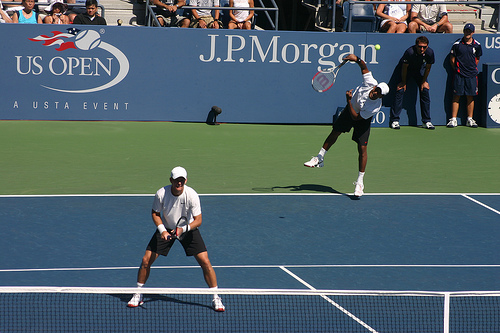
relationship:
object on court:
[204, 106, 223, 126] [2, 119, 499, 332]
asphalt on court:
[1, 121, 499, 194] [2, 119, 499, 332]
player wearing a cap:
[126, 165, 225, 312] [169, 166, 188, 180]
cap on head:
[169, 166, 188, 180] [170, 168, 188, 193]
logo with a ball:
[16, 28, 131, 97] [74, 29, 100, 54]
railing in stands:
[142, 1, 280, 28] [1, 1, 497, 34]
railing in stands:
[292, 1, 496, 32] [1, 1, 497, 34]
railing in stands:
[0, 3, 105, 26] [1, 1, 497, 34]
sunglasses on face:
[417, 45, 428, 51] [416, 41, 428, 56]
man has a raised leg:
[304, 54, 390, 199] [302, 106, 353, 170]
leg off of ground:
[302, 106, 353, 170] [2, 121, 499, 333]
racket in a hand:
[310, 59, 348, 94] [343, 53, 358, 65]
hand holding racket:
[343, 53, 358, 65] [310, 59, 348, 94]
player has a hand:
[304, 54, 390, 199] [343, 53, 358, 65]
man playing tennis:
[304, 54, 390, 199] [1, 25, 500, 332]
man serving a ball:
[304, 54, 390, 199] [374, 43, 380, 52]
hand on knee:
[396, 82, 408, 93] [394, 78, 408, 94]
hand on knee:
[420, 79, 431, 93] [419, 79, 429, 96]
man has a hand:
[390, 36, 436, 130] [396, 82, 408, 93]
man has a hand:
[390, 36, 436, 130] [420, 79, 431, 93]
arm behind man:
[449, 40, 459, 69] [446, 25, 486, 129]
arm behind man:
[476, 43, 483, 67] [446, 25, 486, 129]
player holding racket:
[126, 165, 225, 312] [169, 217, 190, 244]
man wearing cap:
[304, 54, 390, 199] [372, 82, 389, 97]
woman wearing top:
[11, 1, 43, 24] [18, 10, 38, 24]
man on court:
[390, 36, 436, 130] [2, 119, 499, 332]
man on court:
[446, 25, 486, 129] [2, 119, 499, 332]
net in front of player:
[1, 286, 499, 332] [126, 165, 225, 312]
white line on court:
[277, 263, 376, 332] [0, 194, 499, 333]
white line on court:
[2, 263, 500, 275] [0, 194, 499, 333]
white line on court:
[463, 194, 500, 215] [0, 194, 499, 333]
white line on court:
[1, 194, 500, 199] [0, 194, 499, 333]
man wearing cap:
[446, 25, 486, 129] [463, 23, 474, 35]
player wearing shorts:
[126, 165, 225, 312] [147, 226, 207, 257]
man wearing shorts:
[304, 54, 390, 199] [332, 106, 371, 146]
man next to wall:
[390, 36, 436, 130] [0, 25, 499, 126]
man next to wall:
[446, 25, 486, 129] [0, 25, 499, 126]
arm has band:
[151, 190, 170, 246] [157, 225, 166, 235]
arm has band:
[169, 191, 203, 238] [180, 225, 191, 233]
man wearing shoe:
[304, 54, 390, 199] [302, 153, 325, 170]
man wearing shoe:
[304, 54, 390, 199] [353, 182, 366, 202]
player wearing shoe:
[126, 165, 225, 312] [127, 296, 144, 308]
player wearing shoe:
[126, 165, 225, 312] [209, 294, 226, 313]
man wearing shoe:
[390, 36, 436, 130] [392, 121, 401, 132]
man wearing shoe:
[390, 36, 436, 130] [423, 121, 436, 127]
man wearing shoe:
[446, 25, 486, 129] [444, 117, 458, 129]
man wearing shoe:
[446, 25, 486, 129] [466, 115, 477, 129]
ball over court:
[374, 43, 380, 52] [0, 194, 499, 333]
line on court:
[279, 263, 377, 332] [0, 194, 499, 333]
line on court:
[463, 194, 500, 218] [0, 194, 499, 333]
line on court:
[4, 264, 500, 274] [0, 194, 499, 333]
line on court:
[1, 194, 500, 198] [0, 194, 499, 333]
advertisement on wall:
[15, 26, 130, 96] [0, 25, 499, 126]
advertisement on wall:
[197, 32, 381, 77] [0, 25, 499, 126]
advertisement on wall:
[483, 36, 500, 87] [0, 25, 499, 126]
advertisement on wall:
[12, 98, 132, 113] [0, 25, 499, 126]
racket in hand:
[310, 59, 348, 94] [343, 53, 358, 65]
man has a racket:
[304, 54, 390, 199] [310, 59, 348, 94]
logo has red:
[16, 28, 131, 97] [54, 44, 74, 53]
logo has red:
[16, 28, 131, 97] [45, 38, 59, 45]